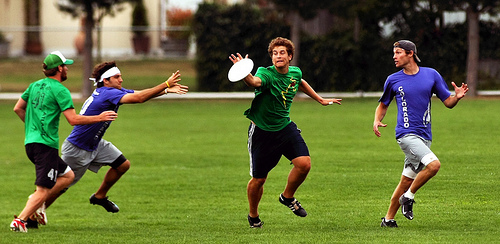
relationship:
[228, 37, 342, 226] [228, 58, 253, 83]
man reaching for frisbee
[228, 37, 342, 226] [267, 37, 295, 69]
man has a head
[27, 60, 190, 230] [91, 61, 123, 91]
man has a head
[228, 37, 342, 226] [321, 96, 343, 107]
man has a hand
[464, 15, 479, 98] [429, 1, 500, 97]
trunk of a tree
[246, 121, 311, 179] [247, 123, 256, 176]
shorts have stripes